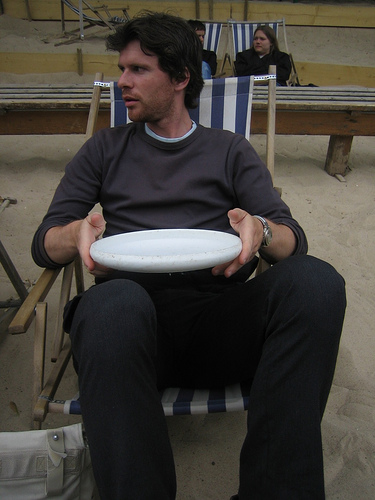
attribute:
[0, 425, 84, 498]
purse — here, beige, messenger bag, white, strapped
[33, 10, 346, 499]
man — light-skinned, here, seated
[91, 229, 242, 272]
frisbee — round, upside down, white in color, plastic, white colored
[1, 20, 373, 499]
sand — ground, covering ground, beige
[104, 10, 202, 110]
hair — shaggy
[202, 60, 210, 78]
jeans — here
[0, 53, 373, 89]
board — yellow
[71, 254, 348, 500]
pants — long, black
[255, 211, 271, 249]
watch — silver, metallic, metal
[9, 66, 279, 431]
chair — here, wooden, beach chair, blue, white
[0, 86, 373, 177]
bench — here, wooden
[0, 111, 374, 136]
beam — wood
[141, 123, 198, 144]
shirt — grey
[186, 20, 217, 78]
man — seated